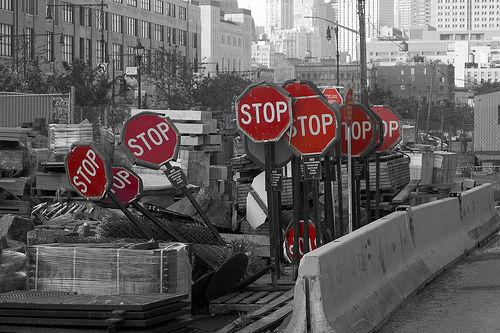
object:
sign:
[287, 114, 333, 141]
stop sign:
[127, 122, 170, 156]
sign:
[73, 149, 100, 193]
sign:
[105, 170, 133, 199]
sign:
[241, 101, 287, 125]